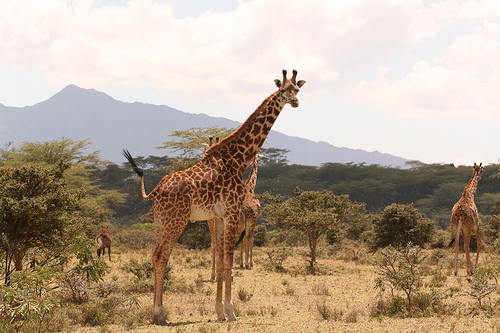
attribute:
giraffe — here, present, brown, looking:
[120, 69, 308, 322]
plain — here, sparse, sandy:
[1, 242, 499, 333]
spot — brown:
[252, 124, 263, 136]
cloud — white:
[7, 0, 500, 164]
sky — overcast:
[1, 0, 500, 165]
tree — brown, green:
[260, 186, 372, 275]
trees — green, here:
[2, 128, 500, 271]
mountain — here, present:
[1, 86, 427, 170]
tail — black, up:
[122, 149, 153, 202]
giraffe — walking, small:
[449, 162, 485, 278]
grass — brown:
[2, 247, 500, 332]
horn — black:
[281, 69, 289, 85]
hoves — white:
[224, 303, 238, 322]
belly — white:
[188, 204, 220, 221]